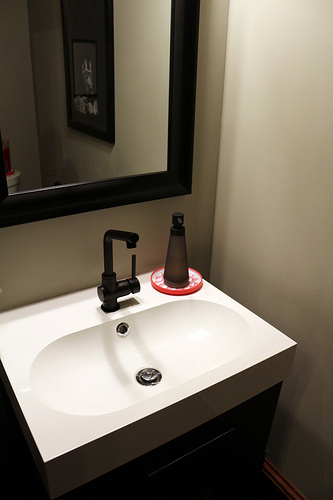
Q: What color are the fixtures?
A: Black.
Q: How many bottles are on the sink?
A: One.